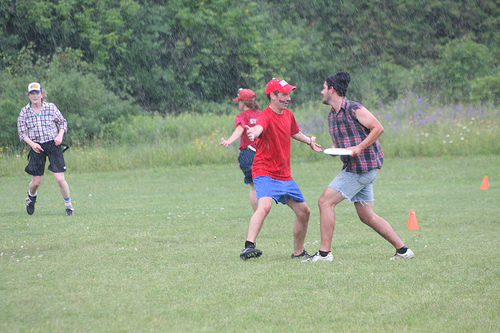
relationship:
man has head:
[309, 67, 413, 268] [319, 69, 353, 113]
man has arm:
[309, 67, 413, 268] [349, 101, 386, 162]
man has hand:
[309, 67, 413, 268] [350, 142, 365, 157]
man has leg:
[309, 67, 413, 268] [312, 157, 361, 273]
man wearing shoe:
[239, 61, 317, 272] [239, 241, 264, 261]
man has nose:
[309, 67, 413, 268] [317, 87, 327, 93]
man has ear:
[309, 67, 413, 268] [327, 82, 338, 95]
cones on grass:
[404, 208, 420, 232] [3, 170, 497, 331]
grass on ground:
[3, 170, 497, 331] [3, 133, 497, 332]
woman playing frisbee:
[217, 88, 262, 213] [323, 143, 358, 157]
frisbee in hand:
[323, 143, 358, 157] [350, 142, 365, 157]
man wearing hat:
[309, 67, 413, 268] [326, 69, 352, 95]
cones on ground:
[399, 164, 494, 233] [3, 133, 497, 332]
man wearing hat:
[239, 61, 317, 272] [263, 78, 299, 94]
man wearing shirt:
[239, 61, 317, 272] [250, 104, 304, 181]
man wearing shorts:
[309, 67, 413, 268] [328, 162, 383, 205]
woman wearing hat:
[223, 80, 282, 208] [232, 86, 254, 101]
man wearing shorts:
[14, 72, 81, 221] [22, 142, 67, 174]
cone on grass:
[479, 171, 492, 195] [3, 170, 497, 331]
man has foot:
[239, 61, 317, 272] [239, 239, 265, 260]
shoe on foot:
[239, 241, 264, 261] [239, 239, 265, 260]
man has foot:
[309, 67, 413, 268] [308, 251, 333, 263]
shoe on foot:
[305, 251, 333, 263] [308, 251, 333, 263]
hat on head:
[263, 78, 299, 94] [264, 77, 298, 112]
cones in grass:
[404, 208, 420, 232] [3, 170, 497, 331]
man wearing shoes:
[239, 61, 317, 272] [241, 236, 310, 265]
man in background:
[14, 72, 81, 221] [2, 30, 493, 239]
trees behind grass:
[3, 4, 491, 137] [3, 170, 497, 331]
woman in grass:
[217, 88, 262, 213] [3, 170, 497, 331]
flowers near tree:
[375, 91, 487, 143] [355, 5, 499, 124]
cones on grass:
[399, 164, 494, 233] [3, 170, 497, 331]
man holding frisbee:
[309, 67, 413, 268] [323, 143, 358, 157]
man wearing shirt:
[309, 67, 413, 268] [325, 101, 385, 170]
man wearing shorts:
[239, 61, 317, 272] [254, 173, 307, 203]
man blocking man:
[239, 61, 317, 272] [309, 67, 413, 268]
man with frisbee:
[309, 67, 413, 268] [323, 143, 358, 157]